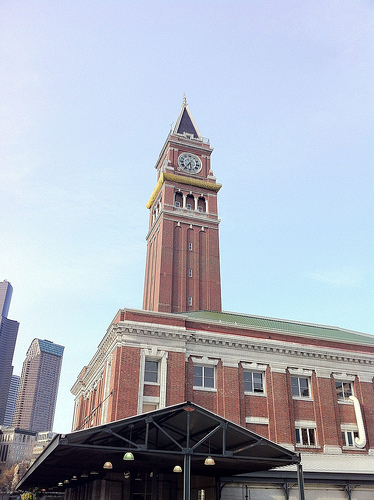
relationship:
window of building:
[191, 356, 217, 392] [69, 89, 373, 498]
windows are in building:
[165, 182, 220, 213] [69, 89, 373, 498]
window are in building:
[243, 371, 263, 391] [69, 89, 373, 498]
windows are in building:
[283, 367, 289, 449] [0, 85, 371, 498]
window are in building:
[191, 356, 217, 392] [0, 85, 371, 498]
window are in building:
[332, 371, 355, 406] [0, 85, 371, 498]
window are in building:
[287, 364, 313, 399] [0, 85, 371, 498]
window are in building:
[241, 362, 267, 398] [0, 85, 371, 498]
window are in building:
[291, 424, 319, 449] [69, 89, 373, 498]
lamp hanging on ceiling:
[203, 455, 215, 465] [18, 408, 294, 490]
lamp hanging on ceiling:
[173, 464, 181, 473] [18, 408, 294, 490]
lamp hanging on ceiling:
[123, 450, 135, 461] [18, 408, 294, 490]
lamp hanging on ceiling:
[102, 461, 113, 468] [18, 408, 294, 490]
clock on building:
[177, 152, 202, 175] [64, 91, 344, 471]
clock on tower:
[177, 152, 202, 175] [142, 104, 222, 312]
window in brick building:
[144, 360, 159, 382] [68, 88, 366, 444]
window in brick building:
[191, 356, 217, 392] [68, 88, 366, 444]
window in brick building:
[241, 362, 267, 398] [68, 88, 366, 444]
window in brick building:
[288, 368, 314, 402] [68, 88, 366, 444]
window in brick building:
[332, 371, 355, 406] [68, 88, 366, 444]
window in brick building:
[288, 368, 314, 402] [69, 303, 373, 454]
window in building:
[191, 356, 217, 392] [63, 78, 341, 449]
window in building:
[241, 362, 267, 398] [69, 89, 373, 498]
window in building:
[143, 358, 157, 382] [69, 89, 373, 498]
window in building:
[191, 364, 216, 389] [69, 89, 373, 498]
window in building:
[332, 371, 355, 406] [69, 89, 373, 498]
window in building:
[288, 368, 314, 402] [69, 89, 373, 498]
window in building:
[241, 362, 267, 398] [63, 78, 341, 449]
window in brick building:
[326, 368, 366, 410] [70, 84, 371, 497]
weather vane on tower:
[182, 92, 187, 104] [142, 104, 222, 312]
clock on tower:
[177, 152, 202, 175] [137, 93, 225, 316]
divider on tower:
[155, 178, 203, 190] [123, 96, 261, 290]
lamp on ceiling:
[204, 456, 216, 465] [48, 399, 293, 451]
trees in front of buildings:
[8, 458, 47, 496] [5, 123, 352, 493]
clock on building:
[156, 146, 216, 195] [124, 93, 221, 358]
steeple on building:
[170, 93, 203, 138] [69, 306, 372, 498]